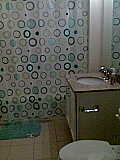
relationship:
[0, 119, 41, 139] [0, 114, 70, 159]
bath mat on floor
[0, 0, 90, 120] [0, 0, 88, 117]
curtain has white background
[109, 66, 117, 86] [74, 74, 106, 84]
bottle side sink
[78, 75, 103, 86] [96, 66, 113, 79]
bathroom sink has faucet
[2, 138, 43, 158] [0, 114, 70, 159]
tile on floor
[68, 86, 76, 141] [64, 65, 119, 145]
door on sink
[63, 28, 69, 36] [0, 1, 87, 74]
circle on shower curtain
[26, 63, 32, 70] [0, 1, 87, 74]
circle on shower curtain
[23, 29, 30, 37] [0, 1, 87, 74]
circle on shower curtain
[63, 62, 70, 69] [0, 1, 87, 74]
circle on shower curtain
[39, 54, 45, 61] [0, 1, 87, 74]
circle on shower curtain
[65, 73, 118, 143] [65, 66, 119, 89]
counter under sink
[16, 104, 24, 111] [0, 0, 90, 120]
circle on curtain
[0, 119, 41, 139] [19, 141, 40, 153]
bath mat on floor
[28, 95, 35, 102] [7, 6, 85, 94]
circle on curtain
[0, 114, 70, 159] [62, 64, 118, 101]
floor next to sink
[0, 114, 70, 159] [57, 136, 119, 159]
floor next to toilet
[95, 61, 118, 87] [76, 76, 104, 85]
faucet above sink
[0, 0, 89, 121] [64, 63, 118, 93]
shower curtain next to sink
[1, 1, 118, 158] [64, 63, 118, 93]
bathroom has sink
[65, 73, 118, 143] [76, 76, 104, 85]
counter has sink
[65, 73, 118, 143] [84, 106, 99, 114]
counter has holder